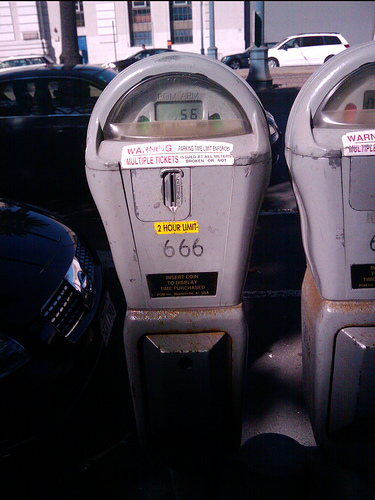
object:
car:
[268, 32, 352, 70]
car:
[100, 45, 181, 68]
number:
[189, 233, 207, 256]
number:
[176, 235, 191, 255]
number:
[162, 237, 175, 257]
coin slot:
[162, 164, 184, 213]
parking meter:
[85, 47, 280, 489]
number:
[187, 107, 200, 118]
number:
[178, 106, 190, 120]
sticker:
[152, 217, 197, 233]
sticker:
[118, 155, 235, 167]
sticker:
[118, 139, 233, 155]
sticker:
[339, 129, 373, 143]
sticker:
[341, 143, 373, 156]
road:
[272, 68, 284, 79]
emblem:
[72, 266, 92, 293]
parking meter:
[283, 39, 374, 498]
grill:
[40, 272, 86, 336]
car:
[3, 201, 114, 394]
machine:
[84, 52, 276, 497]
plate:
[92, 288, 120, 353]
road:
[302, 64, 314, 85]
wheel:
[267, 59, 280, 68]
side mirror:
[281, 45, 289, 51]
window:
[278, 40, 298, 49]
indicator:
[343, 44, 353, 50]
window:
[173, 0, 190, 43]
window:
[130, 0, 151, 45]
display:
[153, 102, 200, 121]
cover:
[103, 71, 251, 139]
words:
[121, 139, 235, 165]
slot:
[162, 167, 185, 210]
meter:
[81, 51, 275, 491]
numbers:
[162, 237, 205, 260]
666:
[163, 236, 206, 257]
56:
[178, 101, 197, 119]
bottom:
[1, 483, 374, 495]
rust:
[302, 273, 322, 322]